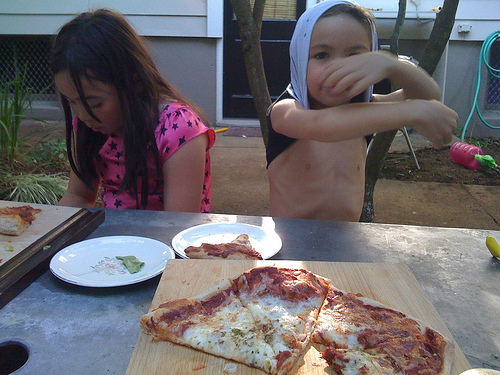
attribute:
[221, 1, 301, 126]
door — black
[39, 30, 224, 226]
girl — young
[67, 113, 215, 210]
shirt — pulled up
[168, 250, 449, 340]
board — tan, wooden, cutting board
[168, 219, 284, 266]
plate — white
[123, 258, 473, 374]
board — wooden 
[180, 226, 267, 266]
pizza — white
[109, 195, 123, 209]
star — black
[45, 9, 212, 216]
girl — little, dark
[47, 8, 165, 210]
hair — long 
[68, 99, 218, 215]
shirt — pink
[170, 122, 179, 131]
star — black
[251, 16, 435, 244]
child — funny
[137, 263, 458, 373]
pizza — fresh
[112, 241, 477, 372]
slab — wooden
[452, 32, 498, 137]
hose — wound, green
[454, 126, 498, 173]
toy — pink, green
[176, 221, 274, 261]
plate — white 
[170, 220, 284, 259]
plate — white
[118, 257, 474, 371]
block — wooden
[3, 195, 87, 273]
block — wooden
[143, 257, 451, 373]
board — cutting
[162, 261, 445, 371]
pizza — cheese